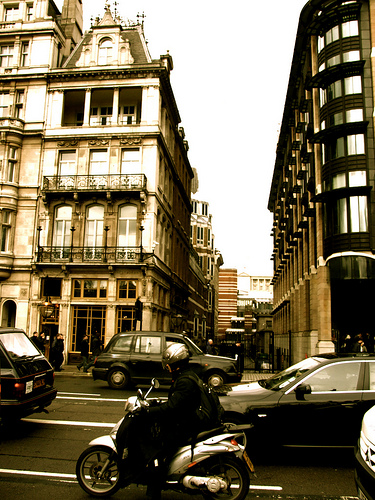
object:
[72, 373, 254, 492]
motorcycle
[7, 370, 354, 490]
street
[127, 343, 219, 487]
person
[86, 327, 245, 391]
car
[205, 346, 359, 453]
car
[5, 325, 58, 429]
car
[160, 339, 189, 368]
helmet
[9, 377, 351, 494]
street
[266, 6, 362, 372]
building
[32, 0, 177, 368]
building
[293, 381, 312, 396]
mirror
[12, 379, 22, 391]
light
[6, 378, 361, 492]
road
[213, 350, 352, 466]
car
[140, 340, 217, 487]
person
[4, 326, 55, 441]
car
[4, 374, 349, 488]
road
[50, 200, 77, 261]
window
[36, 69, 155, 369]
storefront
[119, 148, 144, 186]
window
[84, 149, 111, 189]
window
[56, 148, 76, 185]
window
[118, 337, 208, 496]
man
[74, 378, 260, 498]
motorcycle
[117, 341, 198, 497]
man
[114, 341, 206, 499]
man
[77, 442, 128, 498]
wheel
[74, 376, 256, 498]
scooter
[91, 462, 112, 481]
rotor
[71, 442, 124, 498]
wheel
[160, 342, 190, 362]
helmet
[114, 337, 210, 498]
person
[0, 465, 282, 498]
line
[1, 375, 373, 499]
street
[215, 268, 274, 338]
buildings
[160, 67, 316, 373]
alley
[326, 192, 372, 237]
window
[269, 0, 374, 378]
building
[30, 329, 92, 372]
pedestrians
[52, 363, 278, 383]
sidewalk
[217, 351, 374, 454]
car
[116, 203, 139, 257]
window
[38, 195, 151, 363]
storefront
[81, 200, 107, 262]
window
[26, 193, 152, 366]
storefront